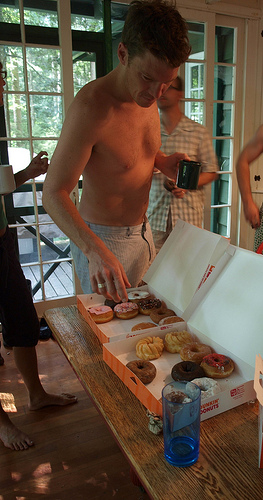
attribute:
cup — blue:
[160, 377, 200, 467]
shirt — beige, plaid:
[139, 108, 226, 250]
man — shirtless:
[56, 105, 157, 218]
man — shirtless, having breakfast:
[37, 7, 191, 295]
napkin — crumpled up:
[146, 409, 163, 435]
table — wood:
[41, 302, 261, 497]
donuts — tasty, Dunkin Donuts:
[72, 219, 258, 424]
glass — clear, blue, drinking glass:
[161, 381, 202, 466]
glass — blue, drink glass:
[173, 157, 201, 193]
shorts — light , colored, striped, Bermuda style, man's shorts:
[249, 202, 261, 267]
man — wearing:
[31, 5, 230, 308]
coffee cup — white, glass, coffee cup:
[0, 162, 15, 193]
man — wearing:
[148, 94, 210, 236]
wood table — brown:
[41, 306, 258, 498]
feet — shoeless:
[35, 377, 88, 410]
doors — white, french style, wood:
[1, 0, 252, 318]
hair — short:
[119, 1, 192, 69]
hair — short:
[175, 74, 182, 89]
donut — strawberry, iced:
[86, 304, 113, 323]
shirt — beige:
[147, 114, 216, 229]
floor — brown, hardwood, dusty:
[0, 323, 151, 497]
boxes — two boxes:
[76, 219, 261, 430]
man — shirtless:
[80, 24, 172, 184]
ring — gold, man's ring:
[181, 189, 187, 195]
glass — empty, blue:
[160, 379, 199, 467]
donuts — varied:
[95, 287, 231, 399]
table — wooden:
[34, 295, 253, 482]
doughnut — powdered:
[138, 329, 194, 355]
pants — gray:
[66, 221, 157, 292]